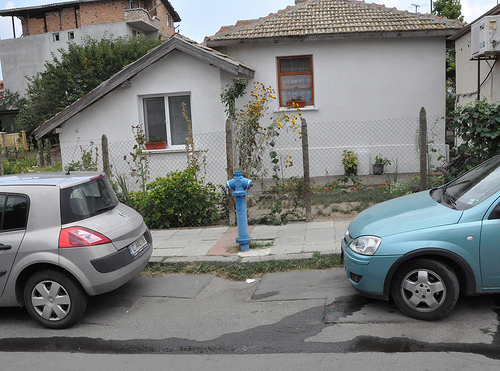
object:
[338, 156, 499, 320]
blue car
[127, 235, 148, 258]
license plate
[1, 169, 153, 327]
car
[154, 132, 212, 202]
fence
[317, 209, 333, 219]
green plants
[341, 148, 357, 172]
green plant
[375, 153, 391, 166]
green plant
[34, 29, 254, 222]
grey house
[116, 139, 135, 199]
metallic fence.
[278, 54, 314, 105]
window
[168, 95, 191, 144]
window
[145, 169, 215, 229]
bush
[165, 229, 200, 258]
ground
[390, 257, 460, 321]
wheel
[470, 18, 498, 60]
unit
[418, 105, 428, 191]
post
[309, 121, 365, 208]
fence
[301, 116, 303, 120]
flowers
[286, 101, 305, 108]
flower pot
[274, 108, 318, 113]
window sill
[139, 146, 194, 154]
window sill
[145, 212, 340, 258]
sidewalk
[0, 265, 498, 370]
street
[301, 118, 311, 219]
post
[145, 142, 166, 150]
box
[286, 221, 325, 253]
ground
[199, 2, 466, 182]
house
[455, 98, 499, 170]
plant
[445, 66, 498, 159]
fence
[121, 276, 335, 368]
pavement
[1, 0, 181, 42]
house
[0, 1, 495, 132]
background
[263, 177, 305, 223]
plant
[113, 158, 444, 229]
front yard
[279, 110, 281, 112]
flowers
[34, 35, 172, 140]
roof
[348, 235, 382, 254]
headlight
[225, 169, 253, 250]
fire hydrant